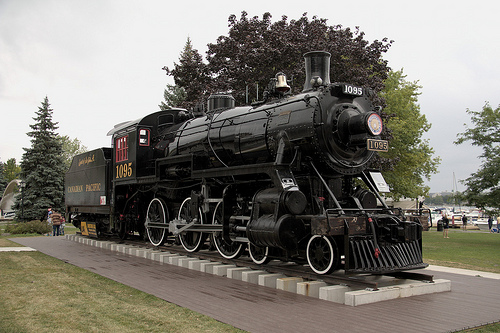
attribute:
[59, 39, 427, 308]
train engine — old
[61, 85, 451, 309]
train/display — black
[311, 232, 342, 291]
wheel — small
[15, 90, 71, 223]
tree — Tall, evergreen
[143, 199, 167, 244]
wheel — big 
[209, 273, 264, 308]
water — Puddle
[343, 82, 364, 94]
number — white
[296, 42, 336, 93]
pipe — exhaust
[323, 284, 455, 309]
bricks — Large, cement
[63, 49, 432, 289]
locomotive — single, black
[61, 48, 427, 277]
train — old, black, older